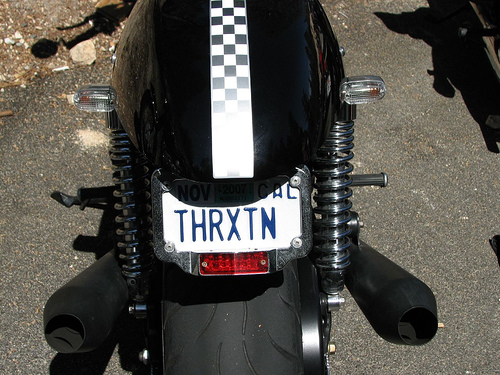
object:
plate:
[161, 192, 301, 251]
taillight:
[200, 250, 269, 275]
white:
[210, 116, 254, 179]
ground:
[0, 1, 499, 374]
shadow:
[375, 2, 497, 155]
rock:
[68, 37, 99, 68]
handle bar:
[53, 5, 131, 50]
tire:
[158, 286, 303, 375]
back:
[111, 0, 324, 276]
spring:
[316, 119, 359, 274]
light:
[345, 76, 391, 105]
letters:
[171, 209, 278, 243]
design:
[206, 5, 252, 178]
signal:
[74, 82, 115, 112]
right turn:
[235, 1, 497, 374]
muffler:
[349, 231, 441, 347]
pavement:
[1, 2, 498, 369]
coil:
[106, 133, 147, 278]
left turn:
[0, 0, 205, 375]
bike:
[27, 0, 438, 373]